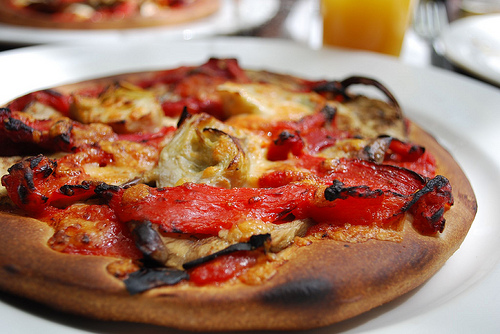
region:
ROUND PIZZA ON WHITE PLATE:
[34, 72, 461, 303]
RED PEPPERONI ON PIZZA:
[184, 176, 256, 236]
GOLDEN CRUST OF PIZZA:
[130, 289, 320, 321]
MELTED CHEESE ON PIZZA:
[88, 149, 149, 180]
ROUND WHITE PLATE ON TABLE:
[11, 42, 499, 311]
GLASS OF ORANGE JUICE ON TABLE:
[330, 4, 409, 57]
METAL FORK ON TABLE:
[407, 8, 467, 81]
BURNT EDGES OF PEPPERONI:
[54, 173, 116, 201]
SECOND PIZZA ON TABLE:
[3, 7, 215, 29]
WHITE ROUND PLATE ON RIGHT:
[429, 19, 497, 84]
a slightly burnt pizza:
[7, 44, 486, 324]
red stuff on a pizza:
[20, 68, 415, 257]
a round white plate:
[2, 35, 495, 332]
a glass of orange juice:
[314, 2, 424, 67]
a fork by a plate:
[412, 7, 467, 82]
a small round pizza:
[4, 29, 488, 332]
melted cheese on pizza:
[37, 55, 432, 307]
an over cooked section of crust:
[247, 239, 422, 321]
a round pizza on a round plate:
[15, 45, 480, 332]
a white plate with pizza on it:
[5, 37, 496, 274]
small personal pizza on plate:
[22, 42, 466, 329]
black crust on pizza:
[251, 253, 352, 313]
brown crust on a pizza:
[341, 232, 438, 302]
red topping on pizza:
[330, 162, 457, 222]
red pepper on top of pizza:
[132, 179, 290, 239]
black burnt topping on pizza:
[127, 268, 169, 290]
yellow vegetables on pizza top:
[155, 108, 257, 185]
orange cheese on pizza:
[102, 131, 157, 189]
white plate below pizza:
[410, 258, 488, 316]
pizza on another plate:
[0, 0, 197, 30]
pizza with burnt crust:
[0, 44, 482, 331]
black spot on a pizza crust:
[246, 272, 341, 318]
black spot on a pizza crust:
[364, 232, 439, 294]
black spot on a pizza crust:
[117, 258, 188, 301]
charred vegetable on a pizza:
[2, 139, 118, 216]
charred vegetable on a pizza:
[298, 157, 463, 241]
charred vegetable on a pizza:
[0, 104, 92, 155]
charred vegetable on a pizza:
[150, 104, 259, 198]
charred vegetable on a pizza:
[261, 99, 353, 156]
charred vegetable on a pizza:
[155, 66, 231, 121]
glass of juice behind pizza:
[304, 0, 429, 76]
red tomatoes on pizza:
[104, 145, 430, 277]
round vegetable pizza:
[0, 35, 499, 309]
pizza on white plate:
[1, 35, 485, 320]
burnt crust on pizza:
[230, 191, 443, 323]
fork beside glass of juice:
[392, 0, 452, 67]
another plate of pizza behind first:
[0, 0, 278, 43]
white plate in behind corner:
[431, 1, 498, 81]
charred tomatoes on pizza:
[3, 70, 148, 235]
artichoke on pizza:
[137, 90, 298, 215]